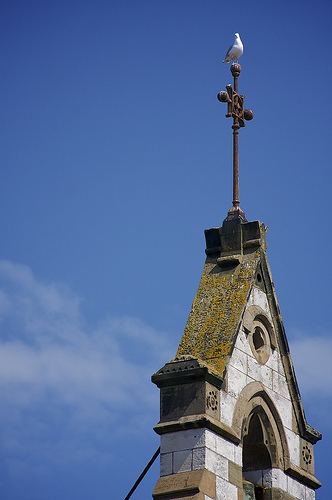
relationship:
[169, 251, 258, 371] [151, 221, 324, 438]
moss on roof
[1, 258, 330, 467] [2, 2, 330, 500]
clouds in sky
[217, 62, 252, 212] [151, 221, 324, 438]
weather vane on roof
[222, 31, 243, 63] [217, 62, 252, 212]
bird on weather vane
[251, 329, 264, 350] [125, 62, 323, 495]
window on building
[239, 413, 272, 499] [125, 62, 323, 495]
window on building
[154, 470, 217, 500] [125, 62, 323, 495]
brown stone on building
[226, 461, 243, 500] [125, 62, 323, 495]
brown stone on building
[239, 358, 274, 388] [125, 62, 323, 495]
stones on building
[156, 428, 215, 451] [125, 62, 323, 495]
stones on building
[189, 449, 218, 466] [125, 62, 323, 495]
stones on building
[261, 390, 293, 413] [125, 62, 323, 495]
stones on building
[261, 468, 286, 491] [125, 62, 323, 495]
stones on building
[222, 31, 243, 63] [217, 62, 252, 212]
bird sitting on weather vane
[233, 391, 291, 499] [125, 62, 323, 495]
arch on building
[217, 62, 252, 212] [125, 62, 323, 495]
weather vane on building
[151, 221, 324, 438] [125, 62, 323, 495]
roof on building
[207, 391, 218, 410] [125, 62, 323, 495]
decorations on building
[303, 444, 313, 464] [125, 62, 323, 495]
decorations on building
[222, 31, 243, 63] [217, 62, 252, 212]
bird perched on weather vane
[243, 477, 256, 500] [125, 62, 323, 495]
bell in building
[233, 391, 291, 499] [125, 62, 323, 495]
arch in building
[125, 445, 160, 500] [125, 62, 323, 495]
brace holding building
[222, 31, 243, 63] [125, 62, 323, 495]
bird on building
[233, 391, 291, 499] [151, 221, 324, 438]
arch in roof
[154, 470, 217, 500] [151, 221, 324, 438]
brown stone on roof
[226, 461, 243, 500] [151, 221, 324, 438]
brown stone on roof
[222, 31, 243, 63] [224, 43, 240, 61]
bird has feathers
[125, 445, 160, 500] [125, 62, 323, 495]
brace behind building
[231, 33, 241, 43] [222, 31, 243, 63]
head on bird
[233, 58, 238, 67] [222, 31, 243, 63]
legs under bird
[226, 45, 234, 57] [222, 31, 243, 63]
wing on bird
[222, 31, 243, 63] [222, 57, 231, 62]
bird has tail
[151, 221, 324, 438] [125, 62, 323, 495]
roof over building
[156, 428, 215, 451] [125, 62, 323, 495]
stones in building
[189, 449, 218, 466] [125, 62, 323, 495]
stones in building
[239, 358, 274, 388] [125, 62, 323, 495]
stones in building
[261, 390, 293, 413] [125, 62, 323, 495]
stones in building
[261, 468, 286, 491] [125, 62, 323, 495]
stones in building